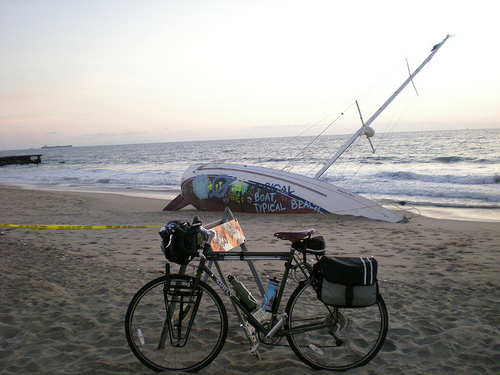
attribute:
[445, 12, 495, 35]
clouds — white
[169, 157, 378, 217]
boat — red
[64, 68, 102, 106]
white clouds — white 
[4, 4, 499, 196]
blue sky — blue 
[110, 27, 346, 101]
clouds — white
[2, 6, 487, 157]
sky — blue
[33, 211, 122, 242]
tape — yellow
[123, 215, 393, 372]
bike — black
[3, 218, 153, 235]
caution tape — yellow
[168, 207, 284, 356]
post — orange , white 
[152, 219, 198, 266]
helmet — black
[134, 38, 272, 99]
clouds — white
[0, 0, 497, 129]
sky — blue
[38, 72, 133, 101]
clouds — white 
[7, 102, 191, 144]
clouds — white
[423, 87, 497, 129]
sky — blue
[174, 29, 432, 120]
clouds — white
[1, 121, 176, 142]
clouds — white 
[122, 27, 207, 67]
clouds — white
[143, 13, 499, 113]
clouds — white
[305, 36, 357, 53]
clouds — white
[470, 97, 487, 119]
clouds — white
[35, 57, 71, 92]
clouds — white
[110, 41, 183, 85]
clouds — white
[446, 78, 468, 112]
clouds — white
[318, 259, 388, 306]
bag — black, beige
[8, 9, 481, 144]
sky — blue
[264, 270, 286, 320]
bottle — blue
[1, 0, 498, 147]
clouds — white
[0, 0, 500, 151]
sky — blue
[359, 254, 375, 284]
stripes — white